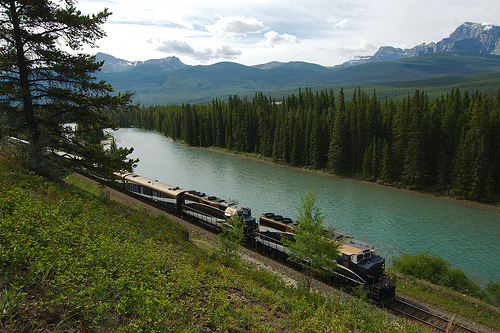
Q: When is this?
A: Daytime.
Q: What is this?
A: Train.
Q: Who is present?
A: No one.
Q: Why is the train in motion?
A: Travelling.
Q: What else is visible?
A: Trees.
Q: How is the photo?
A: Clear.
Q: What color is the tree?
A: Green.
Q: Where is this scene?
A: By the green river.